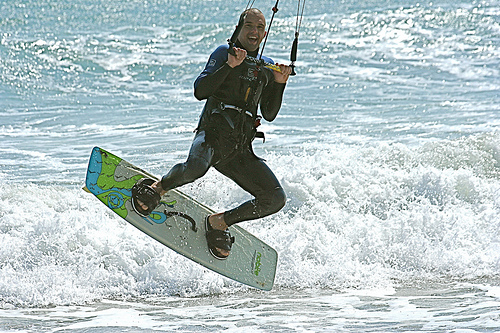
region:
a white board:
[79, 146, 302, 313]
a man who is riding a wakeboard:
[65, 4, 300, 295]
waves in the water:
[328, 117, 464, 277]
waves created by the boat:
[331, 124, 487, 298]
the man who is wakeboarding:
[169, 11, 326, 308]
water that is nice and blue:
[59, 299, 412, 329]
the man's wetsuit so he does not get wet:
[190, 30, 287, 271]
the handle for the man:
[203, 12, 301, 84]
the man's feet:
[130, 181, 256, 261]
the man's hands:
[212, 41, 317, 84]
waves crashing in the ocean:
[300, 136, 433, 266]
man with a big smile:
[232, 7, 278, 56]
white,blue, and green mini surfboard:
[83, 147, 278, 297]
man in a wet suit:
[155, 3, 291, 233]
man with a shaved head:
[222, 2, 287, 52]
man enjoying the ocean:
[77, 4, 327, 299]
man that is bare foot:
[135, 175, 257, 259]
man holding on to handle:
[218, 43, 313, 83]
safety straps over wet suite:
[199, 49, 284, 173]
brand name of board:
[247, 249, 267, 280]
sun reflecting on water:
[340, 8, 475, 33]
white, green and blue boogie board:
[83, 143, 283, 296]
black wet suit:
[163, 41, 287, 227]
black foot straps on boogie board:
[122, 169, 242, 265]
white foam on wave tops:
[310, 147, 459, 259]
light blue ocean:
[30, 22, 171, 129]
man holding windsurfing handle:
[225, 3, 322, 78]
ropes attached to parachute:
[222, 9, 314, 66]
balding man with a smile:
[233, 7, 274, 62]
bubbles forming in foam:
[411, 287, 478, 327]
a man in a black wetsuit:
[128, 7, 346, 259]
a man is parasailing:
[78, 7, 368, 318]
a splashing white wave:
[0, 125, 494, 315]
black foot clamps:
[121, 168, 246, 265]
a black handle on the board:
[161, 201, 203, 235]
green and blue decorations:
[67, 130, 172, 242]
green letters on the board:
[238, 240, 269, 288]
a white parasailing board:
[77, 127, 309, 302]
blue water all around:
[0, 2, 498, 196]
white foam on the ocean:
[0, 271, 497, 322]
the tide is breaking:
[306, 145, 488, 292]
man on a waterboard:
[72, 3, 298, 283]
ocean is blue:
[11, 5, 186, 106]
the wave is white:
[12, 213, 106, 290]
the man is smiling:
[130, 8, 295, 255]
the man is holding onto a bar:
[190, 7, 325, 132]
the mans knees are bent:
[152, 127, 296, 214]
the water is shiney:
[365, 12, 481, 65]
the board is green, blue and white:
[87, 143, 287, 302]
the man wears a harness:
[199, 80, 264, 154]